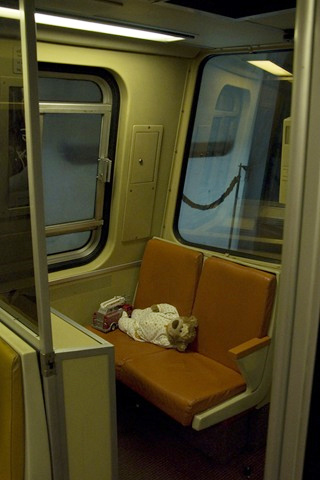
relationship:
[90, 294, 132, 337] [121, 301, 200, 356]
toys and bear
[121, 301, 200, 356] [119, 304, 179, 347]
bear wears a nightie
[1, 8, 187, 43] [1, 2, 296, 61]
light on ceiling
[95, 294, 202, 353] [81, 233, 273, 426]
toys on seat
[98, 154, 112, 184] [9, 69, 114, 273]
handle on window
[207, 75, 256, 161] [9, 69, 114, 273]
reflection of window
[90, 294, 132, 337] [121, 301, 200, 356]
toys and a bear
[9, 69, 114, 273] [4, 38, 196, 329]
window on wall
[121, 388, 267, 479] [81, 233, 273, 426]
floor under seat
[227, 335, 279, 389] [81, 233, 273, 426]
arm rest on seat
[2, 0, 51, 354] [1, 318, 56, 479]
divider by next seat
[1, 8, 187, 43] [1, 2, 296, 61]
light in ceiling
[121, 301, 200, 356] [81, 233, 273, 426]
bear lies on seat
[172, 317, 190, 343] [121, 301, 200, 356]
face on bear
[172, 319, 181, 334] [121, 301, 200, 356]
nose of bear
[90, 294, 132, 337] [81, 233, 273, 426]
toys on a seat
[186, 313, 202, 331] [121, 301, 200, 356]
ear of bear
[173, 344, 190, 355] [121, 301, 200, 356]
ear of bear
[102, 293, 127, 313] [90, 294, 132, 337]
ladder on toys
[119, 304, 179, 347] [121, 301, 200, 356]
nightie on bear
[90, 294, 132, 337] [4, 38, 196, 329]
toys next to wall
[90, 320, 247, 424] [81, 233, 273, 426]
cushion on seat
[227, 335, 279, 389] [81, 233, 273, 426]
arm rest of seat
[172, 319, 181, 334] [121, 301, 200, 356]
nose on bear